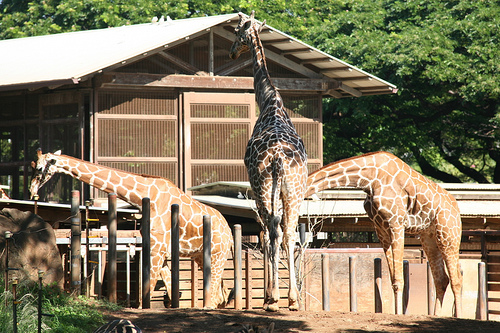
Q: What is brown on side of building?
A: Metal.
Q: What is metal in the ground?
A: Poles.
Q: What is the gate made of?
A: Wood.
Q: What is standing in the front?
A: A giraffe.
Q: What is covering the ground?
A: Dirt.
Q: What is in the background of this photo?
A: Trees.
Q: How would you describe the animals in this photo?
A: Brown and white spotted giraffes.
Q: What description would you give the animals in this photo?
A: Brown and white spotted giraffes.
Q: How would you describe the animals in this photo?
A: Brown and white spotted giraffes.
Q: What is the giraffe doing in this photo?
A: Standing up.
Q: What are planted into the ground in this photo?
A: Poles.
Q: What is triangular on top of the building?
A: The roof.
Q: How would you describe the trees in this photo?
A: The trees are large with green leaves.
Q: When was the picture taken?
A: Daytime.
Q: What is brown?
A: House.